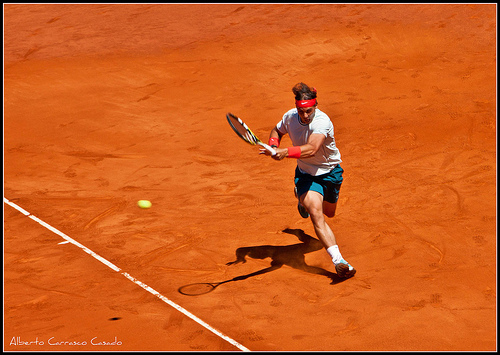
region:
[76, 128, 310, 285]
the ball is green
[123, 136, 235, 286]
the ball is green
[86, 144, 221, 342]
the ball is green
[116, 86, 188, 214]
the ball is green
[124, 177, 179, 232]
A yellow tennis ball in flight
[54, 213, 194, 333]
A white boundary line in dirt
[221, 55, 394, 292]
A male tennis player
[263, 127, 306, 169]
Red wrist bands on man's arms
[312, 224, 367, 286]
A man wearing white tube socks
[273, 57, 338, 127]
A man wearing a red sweat band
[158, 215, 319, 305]
A shadow of a man playing tennis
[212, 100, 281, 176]
A tennis racket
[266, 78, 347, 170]
A man wearing a white t-shirt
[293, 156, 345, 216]
A man wearing blue shorts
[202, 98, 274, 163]
tennis racket in man's hand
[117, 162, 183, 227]
ball in the air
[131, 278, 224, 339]
white line on the ground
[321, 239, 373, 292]
shoe on man's foot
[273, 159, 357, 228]
shorts on the man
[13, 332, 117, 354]
name in the corner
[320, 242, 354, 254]
sock on man's foot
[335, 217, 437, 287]
red court below the man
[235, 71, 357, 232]
man playing a game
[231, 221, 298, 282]
shadow next to man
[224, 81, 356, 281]
man playing tennis on red court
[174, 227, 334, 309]
shadow of the tennis player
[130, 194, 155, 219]
green tennis ball flying across the line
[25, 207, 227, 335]
White line on brown tennis court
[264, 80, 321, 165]
Man wearing red sweat bands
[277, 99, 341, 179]
man wearing white shirt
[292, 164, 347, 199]
man wearing blue shorts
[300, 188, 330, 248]
right muscular leg of person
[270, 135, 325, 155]
left muscular arm of person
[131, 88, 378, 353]
man running to hit tennis ball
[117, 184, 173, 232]
tennis ball in the air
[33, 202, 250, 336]
line in the tennis court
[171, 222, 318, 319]
tennis player's shadow on court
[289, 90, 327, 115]
man's sweat band on head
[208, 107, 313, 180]
man's tennis racquet in hands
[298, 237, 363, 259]
sock on player;s foot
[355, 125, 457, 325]
ground of tennis court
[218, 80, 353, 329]
man running to ball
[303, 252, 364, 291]
bottom of players shoe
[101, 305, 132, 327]
shadow of the tennis ball